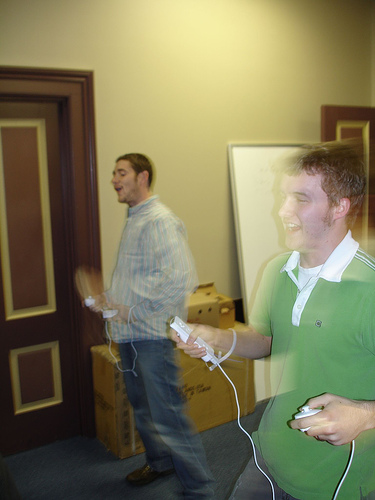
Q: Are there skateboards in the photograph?
A: No, there are no skateboards.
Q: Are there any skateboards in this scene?
A: No, there are no skateboards.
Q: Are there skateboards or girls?
A: No, there are no skateboards or girls.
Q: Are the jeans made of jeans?
A: Yes, the jeans are made of jeans.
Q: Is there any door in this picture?
A: Yes, there is a door.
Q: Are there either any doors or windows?
A: Yes, there is a door.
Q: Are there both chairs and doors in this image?
A: No, there is a door but no chairs.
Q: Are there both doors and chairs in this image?
A: No, there is a door but no chairs.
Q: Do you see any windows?
A: No, there are no windows.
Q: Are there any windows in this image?
A: No, there are no windows.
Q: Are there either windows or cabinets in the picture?
A: No, there are no windows or cabinets.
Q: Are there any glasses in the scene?
A: No, there are no glasses.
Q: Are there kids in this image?
A: No, there are no kids.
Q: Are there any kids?
A: No, there are no kids.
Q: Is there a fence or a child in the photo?
A: No, there are no children or fences.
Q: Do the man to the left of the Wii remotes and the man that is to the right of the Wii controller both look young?
A: Yes, both the man and the man are young.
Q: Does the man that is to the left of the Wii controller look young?
A: Yes, the man is young.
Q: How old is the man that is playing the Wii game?
A: The man is young.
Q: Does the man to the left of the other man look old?
A: No, the man is young.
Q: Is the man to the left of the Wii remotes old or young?
A: The man is young.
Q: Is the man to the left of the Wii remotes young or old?
A: The man is young.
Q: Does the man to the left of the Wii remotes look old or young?
A: The man is young.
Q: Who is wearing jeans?
A: The man is wearing jeans.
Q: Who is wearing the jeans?
A: The man is wearing jeans.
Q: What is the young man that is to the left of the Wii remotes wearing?
A: The man is wearing jeans.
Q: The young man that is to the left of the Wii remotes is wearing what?
A: The man is wearing jeans.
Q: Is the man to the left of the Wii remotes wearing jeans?
A: Yes, the man is wearing jeans.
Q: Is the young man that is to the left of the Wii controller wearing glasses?
A: No, the man is wearing jeans.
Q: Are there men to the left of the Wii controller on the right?
A: Yes, there is a man to the left of the Wii remotes.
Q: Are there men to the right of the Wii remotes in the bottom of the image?
A: No, the man is to the left of the Wii controller.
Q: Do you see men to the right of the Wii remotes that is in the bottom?
A: No, the man is to the left of the Wii controller.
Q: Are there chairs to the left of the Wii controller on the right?
A: No, there is a man to the left of the Wii remotes.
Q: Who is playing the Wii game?
A: The man is playing the Wii game.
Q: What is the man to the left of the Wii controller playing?
A: The man is playing the Wii game.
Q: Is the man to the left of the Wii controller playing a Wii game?
A: Yes, the man is playing a Wii game.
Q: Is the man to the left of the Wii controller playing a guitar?
A: No, the man is playing a Wii game.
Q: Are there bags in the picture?
A: No, there are no bags.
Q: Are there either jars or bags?
A: No, there are no bags or jars.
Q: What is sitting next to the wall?
A: The boxes are sitting next to the wall.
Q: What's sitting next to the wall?
A: The boxes are sitting next to the wall.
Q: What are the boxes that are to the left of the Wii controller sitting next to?
A: The boxes are sitting next to the wall.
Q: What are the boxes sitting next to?
A: The boxes are sitting next to the wall.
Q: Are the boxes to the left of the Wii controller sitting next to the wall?
A: Yes, the boxes are sitting next to the wall.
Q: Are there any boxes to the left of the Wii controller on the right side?
A: Yes, there are boxes to the left of the Wii remotes.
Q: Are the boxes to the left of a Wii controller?
A: Yes, the boxes are to the left of a Wii controller.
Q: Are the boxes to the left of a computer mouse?
A: No, the boxes are to the left of a Wii controller.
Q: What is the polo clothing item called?
A: The clothing item is a polo shirt.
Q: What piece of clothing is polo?
A: The clothing item is a polo shirt.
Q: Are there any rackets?
A: No, there are no rackets.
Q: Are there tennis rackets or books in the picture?
A: No, there are no tennis rackets or books.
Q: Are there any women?
A: No, there are no women.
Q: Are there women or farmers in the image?
A: No, there are no women or farmers.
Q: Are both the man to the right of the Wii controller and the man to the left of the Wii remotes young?
A: Yes, both the man and the man are young.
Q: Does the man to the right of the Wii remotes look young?
A: Yes, the man is young.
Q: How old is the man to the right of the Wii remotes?
A: The man is young.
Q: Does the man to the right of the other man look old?
A: No, the man is young.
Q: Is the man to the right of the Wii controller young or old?
A: The man is young.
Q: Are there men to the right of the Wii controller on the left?
A: Yes, there is a man to the right of the Wii controller.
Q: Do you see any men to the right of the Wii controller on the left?
A: Yes, there is a man to the right of the Wii controller.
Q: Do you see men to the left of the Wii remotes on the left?
A: No, the man is to the right of the Wii controller.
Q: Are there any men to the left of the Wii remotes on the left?
A: No, the man is to the right of the Wii controller.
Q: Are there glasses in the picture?
A: No, there are no glasses.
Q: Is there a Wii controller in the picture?
A: Yes, there is a Wii controller.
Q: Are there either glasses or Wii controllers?
A: Yes, there is a Wii controller.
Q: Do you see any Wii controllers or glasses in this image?
A: Yes, there is a Wii controller.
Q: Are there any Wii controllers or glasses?
A: Yes, there is a Wii controller.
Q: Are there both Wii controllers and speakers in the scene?
A: No, there is a Wii controller but no speakers.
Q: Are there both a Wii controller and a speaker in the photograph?
A: No, there is a Wii controller but no speakers.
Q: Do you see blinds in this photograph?
A: No, there are no blinds.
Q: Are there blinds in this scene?
A: No, there are no blinds.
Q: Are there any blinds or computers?
A: No, there are no blinds or computers.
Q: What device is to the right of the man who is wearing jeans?
A: The device is a Wii controller.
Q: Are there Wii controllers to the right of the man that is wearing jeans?
A: Yes, there is a Wii controller to the right of the man.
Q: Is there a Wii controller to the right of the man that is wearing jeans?
A: Yes, there is a Wii controller to the right of the man.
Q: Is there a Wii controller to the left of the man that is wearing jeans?
A: No, the Wii controller is to the right of the man.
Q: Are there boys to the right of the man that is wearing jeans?
A: No, there is a Wii controller to the right of the man.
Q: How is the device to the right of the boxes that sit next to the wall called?
A: The device is a Wii controller.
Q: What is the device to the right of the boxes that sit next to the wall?
A: The device is a Wii controller.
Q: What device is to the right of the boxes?
A: The device is a Wii controller.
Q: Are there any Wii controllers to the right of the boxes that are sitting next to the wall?
A: Yes, there is a Wii controller to the right of the boxes.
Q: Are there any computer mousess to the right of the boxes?
A: No, there is a Wii controller to the right of the boxes.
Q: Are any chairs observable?
A: No, there are no chairs.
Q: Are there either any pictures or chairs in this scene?
A: No, there are no chairs or pictures.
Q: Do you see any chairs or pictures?
A: No, there are no chairs or pictures.